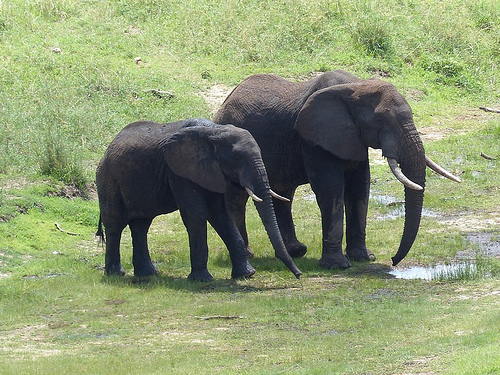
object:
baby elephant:
[93, 120, 304, 283]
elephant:
[88, 66, 462, 284]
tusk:
[243, 187, 293, 204]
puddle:
[373, 261, 477, 283]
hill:
[3, 2, 500, 252]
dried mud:
[322, 193, 352, 268]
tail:
[96, 209, 106, 247]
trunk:
[390, 117, 427, 266]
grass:
[1, 3, 499, 374]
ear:
[161, 124, 228, 195]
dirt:
[2, 318, 258, 363]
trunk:
[248, 156, 303, 280]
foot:
[321, 255, 353, 270]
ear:
[292, 84, 368, 161]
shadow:
[214, 251, 397, 282]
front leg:
[207, 197, 256, 282]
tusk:
[379, 156, 465, 189]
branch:
[54, 220, 83, 238]